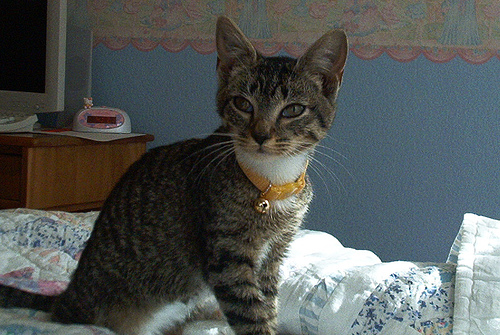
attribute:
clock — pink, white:
[74, 105, 131, 135]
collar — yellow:
[242, 157, 313, 210]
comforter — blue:
[1, 206, 496, 333]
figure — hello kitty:
[56, 89, 113, 113]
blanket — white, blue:
[0, 200, 499, 333]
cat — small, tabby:
[73, 10, 416, 333]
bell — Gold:
[253, 198, 270, 211]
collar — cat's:
[217, 130, 328, 206]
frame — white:
[2, 9, 69, 113]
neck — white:
[229, 134, 318, 181]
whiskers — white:
[176, 118, 362, 216]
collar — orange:
[240, 160, 306, 211]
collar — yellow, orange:
[231, 142, 306, 201]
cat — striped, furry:
[81, 12, 376, 332]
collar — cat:
[234, 152, 308, 207]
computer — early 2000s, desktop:
[1, 5, 126, 100]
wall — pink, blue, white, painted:
[344, 56, 495, 223]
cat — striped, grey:
[0, 17, 350, 332]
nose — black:
[252, 130, 272, 145]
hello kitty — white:
[80, 95, 95, 109]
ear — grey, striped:
[290, 25, 347, 96]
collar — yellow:
[236, 140, 306, 212]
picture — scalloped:
[86, 1, 499, 63]